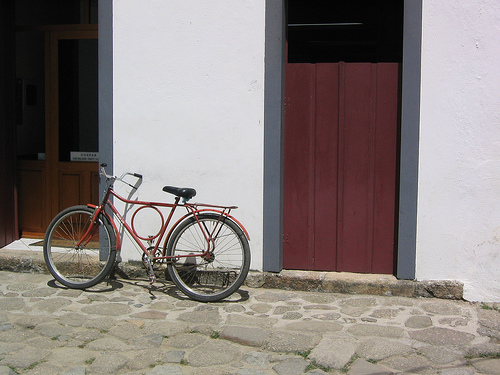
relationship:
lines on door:
[280, 37, 402, 284] [259, 1, 431, 284]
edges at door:
[398, 0, 418, 282] [259, 1, 431, 284]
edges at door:
[258, 1, 288, 277] [259, 1, 431, 284]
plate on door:
[67, 148, 102, 170] [40, 20, 111, 250]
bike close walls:
[29, 156, 257, 307] [113, 5, 267, 275]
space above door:
[41, 1, 101, 29] [40, 20, 111, 250]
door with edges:
[259, 1, 431, 284] [398, 0, 418, 282]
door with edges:
[259, 1, 431, 284] [258, 1, 288, 277]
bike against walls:
[29, 156, 257, 307] [113, 5, 267, 275]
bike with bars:
[29, 156, 257, 307] [99, 161, 144, 185]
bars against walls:
[99, 161, 144, 185] [113, 5, 267, 275]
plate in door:
[67, 148, 102, 170] [40, 20, 111, 250]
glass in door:
[50, 35, 106, 162] [259, 1, 431, 284]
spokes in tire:
[174, 218, 246, 298] [162, 209, 255, 305]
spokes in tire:
[48, 212, 113, 286] [162, 209, 255, 305]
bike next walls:
[29, 156, 257, 307] [113, 5, 267, 275]